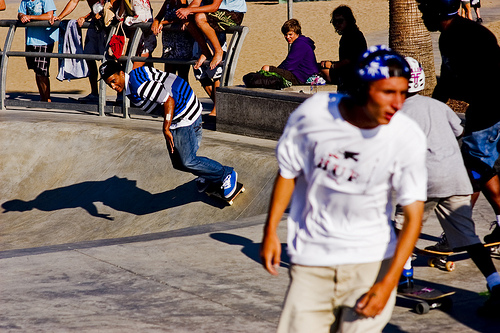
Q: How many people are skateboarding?
A: Four.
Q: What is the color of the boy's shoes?
A: Blue.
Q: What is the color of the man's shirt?
A: White.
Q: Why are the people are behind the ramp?
A: To watch.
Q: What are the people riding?
A: Skateboard.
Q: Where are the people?
A: Behind the skateboard ramp.